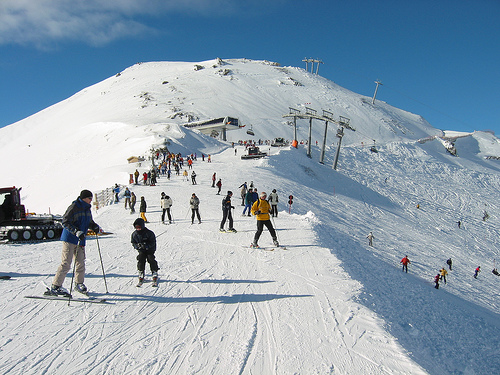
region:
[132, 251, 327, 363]
thick white snow on mountain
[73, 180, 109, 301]
skier on ski slope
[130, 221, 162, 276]
skier on ski slope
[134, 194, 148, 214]
skier on ski slope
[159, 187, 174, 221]
skier on ski slope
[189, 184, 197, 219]
skier on ski slope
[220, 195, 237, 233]
skier on ski slope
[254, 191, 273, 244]
skier on ski slope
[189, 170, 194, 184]
skier on ski slope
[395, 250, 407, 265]
skier on ski slope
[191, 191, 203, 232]
skier on ski slope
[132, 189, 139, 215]
skier on ski slope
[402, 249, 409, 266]
skier on ski slope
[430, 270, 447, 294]
skier on ski slope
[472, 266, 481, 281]
skier on ski slope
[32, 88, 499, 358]
Alot of skiers on mountain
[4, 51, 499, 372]
Large mountain with snow on top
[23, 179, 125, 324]
Man teaching kid how to ski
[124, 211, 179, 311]
Little kid learning how to ski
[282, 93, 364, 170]
Four ski lift poles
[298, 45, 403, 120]
Four poles on the top of the mountain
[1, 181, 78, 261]
Snow machin in the background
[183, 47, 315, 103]
grey rocks on top of the mountain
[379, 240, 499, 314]
Group of skiers on the bottom of the mountain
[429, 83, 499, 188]
Small hill off to the side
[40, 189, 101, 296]
skier in snow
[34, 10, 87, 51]
white snow on hill side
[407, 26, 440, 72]
white snow on hill side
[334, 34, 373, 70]
white snow on hill side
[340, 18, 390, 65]
white snow on hill side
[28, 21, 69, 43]
white snow on hill side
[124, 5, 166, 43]
white snow on hill side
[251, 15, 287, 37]
white snow on hill side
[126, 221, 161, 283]
person wearing black pants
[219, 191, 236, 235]
person wearing black pants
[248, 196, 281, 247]
person wearing black pants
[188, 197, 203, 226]
person wearing black pants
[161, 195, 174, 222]
person wearing black pants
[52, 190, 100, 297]
person wearing white pants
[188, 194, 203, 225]
person wearing white jacket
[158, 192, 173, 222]
person wearing white jacket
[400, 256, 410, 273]
person wearing red jacket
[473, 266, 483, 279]
person wearing red jacket